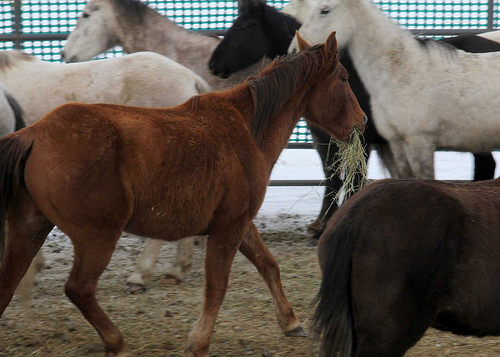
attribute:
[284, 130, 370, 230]
grass — green, light green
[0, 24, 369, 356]
horse — brown, in a barn, in barn, reddish brown, grouped, dark brown, white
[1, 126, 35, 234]
tail — brown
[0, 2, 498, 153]
fencing — blue, in the background, metal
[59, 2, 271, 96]
horse — white, grayish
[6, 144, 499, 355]
ground — dirty, dirt, brown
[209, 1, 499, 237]
horse — black